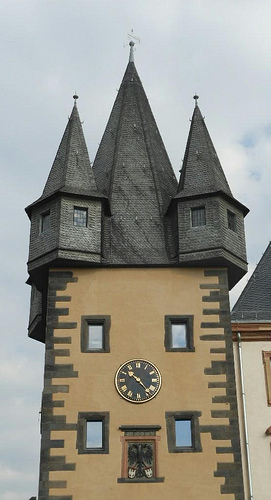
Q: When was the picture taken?
A: The day.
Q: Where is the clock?
A: On building.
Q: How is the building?
A: Old.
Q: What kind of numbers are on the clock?
A: Roman numeral.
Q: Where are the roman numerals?
A: On clock.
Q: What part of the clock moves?
A: Hands.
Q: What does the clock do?
A: Tell time.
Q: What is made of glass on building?
A: Windows.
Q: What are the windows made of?
A: Glass.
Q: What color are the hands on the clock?
A: Gold.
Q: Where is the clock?
A: The building.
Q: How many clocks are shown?
A: One.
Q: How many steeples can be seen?
A: Three.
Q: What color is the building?
A: Tan.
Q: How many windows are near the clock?
A: Four.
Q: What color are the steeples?
A: Gray.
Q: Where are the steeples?
A: Above building.